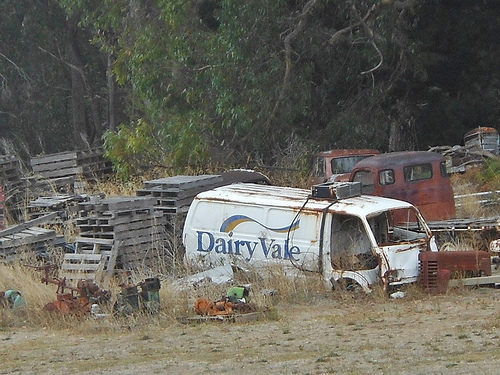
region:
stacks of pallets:
[6, 127, 237, 317]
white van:
[172, 158, 426, 302]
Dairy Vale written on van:
[194, 216, 314, 272]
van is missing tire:
[317, 266, 380, 297]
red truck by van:
[343, 146, 473, 219]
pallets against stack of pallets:
[63, 229, 136, 292]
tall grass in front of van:
[228, 257, 343, 316]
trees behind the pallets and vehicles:
[86, 18, 347, 195]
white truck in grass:
[182, 167, 431, 311]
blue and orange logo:
[200, 219, 303, 276]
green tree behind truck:
[102, 10, 317, 145]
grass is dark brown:
[221, 259, 441, 353]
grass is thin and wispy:
[153, 270, 436, 348]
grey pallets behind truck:
[2, 150, 227, 312]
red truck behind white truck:
[304, 153, 497, 249]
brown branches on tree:
[274, 15, 424, 142]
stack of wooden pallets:
[10, 139, 173, 279]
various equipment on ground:
[1, 251, 261, 353]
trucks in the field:
[31, 115, 448, 295]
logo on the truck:
[180, 224, 300, 273]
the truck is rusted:
[186, 153, 375, 217]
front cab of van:
[335, 218, 423, 278]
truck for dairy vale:
[195, 230, 311, 268]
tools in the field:
[176, 276, 248, 316]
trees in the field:
[132, 48, 214, 130]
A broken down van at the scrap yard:
[186, 184, 438, 296]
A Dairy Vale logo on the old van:
[196, 213, 301, 264]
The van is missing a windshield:
[367, 208, 426, 246]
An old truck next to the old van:
[351, 150, 499, 253]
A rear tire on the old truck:
[438, 234, 459, 252]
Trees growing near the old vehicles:
[0, 1, 499, 185]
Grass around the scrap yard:
[1, 287, 498, 373]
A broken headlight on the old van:
[385, 267, 402, 282]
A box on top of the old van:
[311, 182, 361, 200]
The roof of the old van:
[192, 183, 412, 214]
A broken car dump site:
[0, 0, 498, 373]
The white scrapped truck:
[184, 184, 442, 306]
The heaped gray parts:
[2, 148, 261, 293]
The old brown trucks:
[324, 143, 489, 298]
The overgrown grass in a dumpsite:
[0, 152, 498, 326]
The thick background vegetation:
[0, 0, 499, 172]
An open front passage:
[2, 293, 498, 373]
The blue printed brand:
[186, 207, 318, 260]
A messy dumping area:
[0, 0, 498, 374]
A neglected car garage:
[0, 0, 498, 374]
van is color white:
[185, 183, 432, 294]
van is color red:
[352, 154, 459, 224]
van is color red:
[308, 144, 387, 188]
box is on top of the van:
[303, 177, 369, 217]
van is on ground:
[176, 181, 443, 303]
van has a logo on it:
[218, 212, 303, 239]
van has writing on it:
[194, 234, 299, 263]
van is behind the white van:
[185, 149, 495, 299]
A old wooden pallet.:
[48, 255, 111, 302]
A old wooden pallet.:
[64, 230, 109, 286]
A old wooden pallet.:
[64, 187, 161, 214]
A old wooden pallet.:
[79, 205, 162, 212]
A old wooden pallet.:
[137, 171, 221, 186]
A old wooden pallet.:
[119, 181, 234, 192]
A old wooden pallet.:
[68, 217, 169, 223]